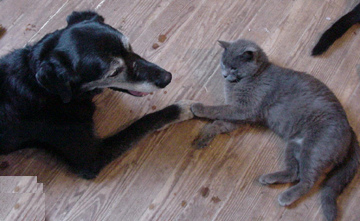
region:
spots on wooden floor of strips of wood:
[3, 8, 344, 212]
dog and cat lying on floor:
[0, 3, 349, 208]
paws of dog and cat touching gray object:
[145, 94, 193, 124]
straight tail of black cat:
[297, 0, 352, 54]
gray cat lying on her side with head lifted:
[189, 27, 351, 212]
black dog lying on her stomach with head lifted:
[0, 5, 175, 181]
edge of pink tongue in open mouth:
[95, 52, 170, 95]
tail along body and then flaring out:
[307, 120, 353, 214]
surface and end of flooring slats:
[0, 167, 44, 216]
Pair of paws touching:
[168, 93, 212, 121]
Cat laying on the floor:
[192, 36, 359, 220]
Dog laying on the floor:
[0, 1, 196, 192]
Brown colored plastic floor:
[0, 0, 359, 219]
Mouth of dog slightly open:
[113, 56, 173, 100]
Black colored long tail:
[308, 6, 357, 59]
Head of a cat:
[213, 32, 268, 87]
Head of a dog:
[45, 11, 173, 102]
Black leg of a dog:
[81, 96, 196, 187]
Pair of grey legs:
[191, 94, 249, 152]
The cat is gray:
[189, 35, 358, 219]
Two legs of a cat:
[256, 144, 324, 209]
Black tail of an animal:
[309, 1, 358, 57]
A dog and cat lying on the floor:
[1, 1, 358, 219]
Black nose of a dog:
[155, 64, 175, 91]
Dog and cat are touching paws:
[38, 6, 268, 182]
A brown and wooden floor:
[1, 1, 358, 219]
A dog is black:
[0, 7, 196, 186]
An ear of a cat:
[239, 41, 260, 65]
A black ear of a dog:
[30, 52, 85, 107]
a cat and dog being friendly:
[0, 4, 359, 219]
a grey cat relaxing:
[190, 16, 358, 218]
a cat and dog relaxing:
[2, 7, 357, 219]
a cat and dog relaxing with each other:
[1, 7, 357, 219]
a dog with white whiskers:
[0, 5, 190, 191]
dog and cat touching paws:
[2, 7, 356, 215]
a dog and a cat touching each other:
[3, 5, 356, 215]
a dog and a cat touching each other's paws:
[3, 6, 358, 218]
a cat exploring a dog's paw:
[5, 8, 359, 213]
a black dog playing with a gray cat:
[3, 4, 357, 219]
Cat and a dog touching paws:
[63, 10, 274, 165]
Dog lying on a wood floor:
[8, 6, 188, 181]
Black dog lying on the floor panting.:
[42, 14, 178, 152]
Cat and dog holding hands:
[142, 96, 222, 159]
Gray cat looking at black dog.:
[44, 7, 297, 184]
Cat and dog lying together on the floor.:
[31, 5, 333, 205]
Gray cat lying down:
[193, 34, 346, 219]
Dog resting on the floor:
[4, 7, 188, 174]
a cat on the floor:
[156, 31, 357, 143]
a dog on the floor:
[18, 5, 152, 144]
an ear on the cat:
[242, 42, 256, 63]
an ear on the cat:
[217, 37, 240, 57]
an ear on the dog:
[51, 14, 114, 23]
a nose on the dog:
[139, 65, 171, 82]